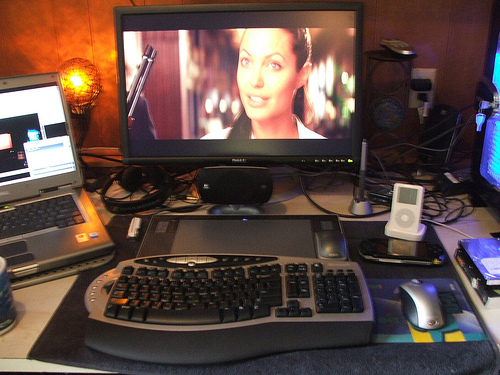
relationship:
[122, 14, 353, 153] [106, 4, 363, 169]
movie on computer monitor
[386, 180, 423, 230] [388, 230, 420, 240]
ipod in charger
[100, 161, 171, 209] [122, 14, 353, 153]
headphones under monitor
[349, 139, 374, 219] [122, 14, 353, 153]
microphone to right of monitor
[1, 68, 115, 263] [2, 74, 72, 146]
laptop on left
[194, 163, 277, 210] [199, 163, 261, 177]
speaker in center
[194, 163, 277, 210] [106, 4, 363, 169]
speaker under monitor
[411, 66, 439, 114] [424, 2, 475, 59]
outlet in wall